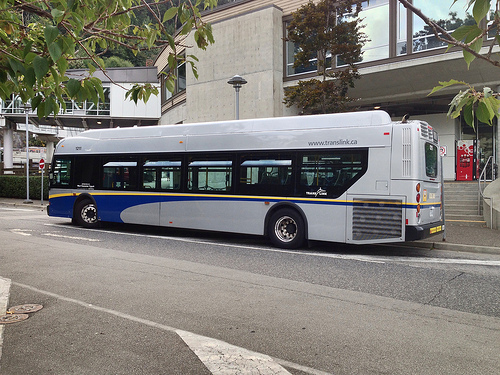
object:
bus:
[45, 108, 447, 250]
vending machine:
[455, 139, 475, 181]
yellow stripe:
[48, 192, 443, 206]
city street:
[0, 197, 497, 375]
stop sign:
[38, 157, 46, 171]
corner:
[0, 174, 47, 236]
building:
[155, 2, 500, 183]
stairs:
[445, 219, 488, 228]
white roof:
[55, 109, 440, 156]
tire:
[263, 202, 308, 249]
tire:
[73, 193, 104, 229]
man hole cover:
[0, 303, 46, 324]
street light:
[226, 74, 248, 92]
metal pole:
[234, 87, 241, 119]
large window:
[282, 0, 500, 83]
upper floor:
[151, 0, 500, 110]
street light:
[18, 101, 34, 111]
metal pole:
[23, 108, 33, 204]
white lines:
[134, 318, 143, 322]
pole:
[41, 169, 44, 205]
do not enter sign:
[439, 144, 447, 156]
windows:
[98, 155, 141, 191]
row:
[47, 145, 393, 200]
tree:
[282, 0, 372, 115]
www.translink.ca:
[307, 138, 358, 147]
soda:
[457, 155, 473, 168]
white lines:
[78, 238, 97, 243]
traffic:
[0, 124, 499, 264]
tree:
[393, 0, 498, 131]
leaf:
[462, 28, 484, 70]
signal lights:
[416, 182, 421, 192]